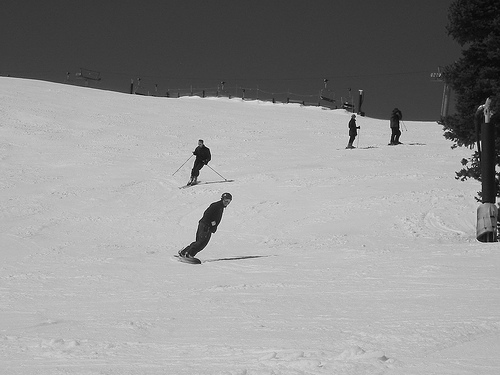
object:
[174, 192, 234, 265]
snowboarder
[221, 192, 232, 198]
helmet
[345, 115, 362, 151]
skier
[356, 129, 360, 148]
poles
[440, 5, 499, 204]
tree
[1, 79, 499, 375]
hill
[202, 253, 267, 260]
shadow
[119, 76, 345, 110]
fence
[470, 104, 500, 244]
cover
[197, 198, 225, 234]
coat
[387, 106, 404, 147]
people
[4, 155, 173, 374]
snow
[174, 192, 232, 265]
man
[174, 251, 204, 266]
snowboard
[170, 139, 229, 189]
man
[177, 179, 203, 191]
skis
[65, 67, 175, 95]
ski lift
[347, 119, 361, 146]
ski suit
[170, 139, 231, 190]
skiers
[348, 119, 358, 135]
jacket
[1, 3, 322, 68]
sky